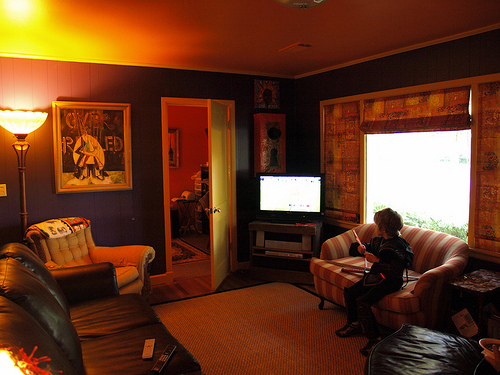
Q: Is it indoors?
A: Yes, it is indoors.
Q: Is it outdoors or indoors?
A: It is indoors.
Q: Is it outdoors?
A: No, it is indoors.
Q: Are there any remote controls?
A: Yes, there is a remote control.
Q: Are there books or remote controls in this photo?
A: Yes, there is a remote control.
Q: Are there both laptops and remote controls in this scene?
A: No, there is a remote control but no laptops.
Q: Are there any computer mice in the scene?
A: No, there are no computer mice.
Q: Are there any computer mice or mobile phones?
A: No, there are no computer mice or mobile phones.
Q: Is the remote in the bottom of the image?
A: Yes, the remote is in the bottom of the image.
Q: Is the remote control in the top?
A: No, the remote control is in the bottom of the image.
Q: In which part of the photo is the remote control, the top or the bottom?
A: The remote control is in the bottom of the image.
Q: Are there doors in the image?
A: Yes, there is a door.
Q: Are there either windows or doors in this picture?
A: Yes, there is a door.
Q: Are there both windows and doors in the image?
A: Yes, there are both a door and a window.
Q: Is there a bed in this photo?
A: No, there are no beds.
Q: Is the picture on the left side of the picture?
A: Yes, the picture is on the left of the image.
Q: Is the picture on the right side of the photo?
A: No, the picture is on the left of the image.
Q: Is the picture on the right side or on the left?
A: The picture is on the left of the image.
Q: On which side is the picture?
A: The picture is on the left of the image.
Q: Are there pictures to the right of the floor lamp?
A: Yes, there is a picture to the right of the floor lamp.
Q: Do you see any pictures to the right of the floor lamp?
A: Yes, there is a picture to the right of the floor lamp.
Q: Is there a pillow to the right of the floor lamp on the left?
A: No, there is a picture to the right of the floor lamp.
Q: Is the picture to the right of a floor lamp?
A: Yes, the picture is to the right of a floor lamp.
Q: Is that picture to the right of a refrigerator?
A: No, the picture is to the right of a floor lamp.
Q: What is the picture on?
A: The picture is on the wall.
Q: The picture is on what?
A: The picture is on the wall.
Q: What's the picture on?
A: The picture is on the wall.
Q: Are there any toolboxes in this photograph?
A: No, there are no toolboxes.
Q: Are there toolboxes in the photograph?
A: No, there are no toolboxes.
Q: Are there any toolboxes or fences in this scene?
A: No, there are no toolboxes or fences.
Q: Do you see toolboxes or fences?
A: No, there are no toolboxes or fences.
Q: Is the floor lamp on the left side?
A: Yes, the floor lamp is on the left of the image.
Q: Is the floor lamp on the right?
A: No, the floor lamp is on the left of the image.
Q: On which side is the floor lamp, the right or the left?
A: The floor lamp is on the left of the image.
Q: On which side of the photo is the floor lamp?
A: The floor lamp is on the left of the image.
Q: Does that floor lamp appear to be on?
A: Yes, the floor lamp is on.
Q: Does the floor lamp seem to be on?
A: Yes, the floor lamp is on.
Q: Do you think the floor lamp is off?
A: No, the floor lamp is on.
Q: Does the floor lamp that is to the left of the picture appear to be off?
A: No, the floor lamp is on.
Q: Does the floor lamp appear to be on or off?
A: The floor lamp is on.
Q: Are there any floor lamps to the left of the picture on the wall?
A: Yes, there is a floor lamp to the left of the picture.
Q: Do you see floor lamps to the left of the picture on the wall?
A: Yes, there is a floor lamp to the left of the picture.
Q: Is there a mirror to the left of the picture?
A: No, there is a floor lamp to the left of the picture.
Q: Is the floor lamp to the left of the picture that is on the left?
A: Yes, the floor lamp is to the left of the picture.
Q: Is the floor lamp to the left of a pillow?
A: No, the floor lamp is to the left of the picture.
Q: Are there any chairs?
A: Yes, there is a chair.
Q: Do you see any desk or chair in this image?
A: Yes, there is a chair.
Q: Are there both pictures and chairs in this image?
A: Yes, there are both a chair and a picture.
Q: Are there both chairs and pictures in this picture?
A: Yes, there are both a chair and a picture.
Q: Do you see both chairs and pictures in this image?
A: Yes, there are both a chair and a picture.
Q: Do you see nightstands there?
A: No, there are no nightstands.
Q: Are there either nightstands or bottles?
A: No, there are no nightstands or bottles.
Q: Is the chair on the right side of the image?
A: Yes, the chair is on the right of the image.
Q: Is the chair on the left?
A: No, the chair is on the right of the image.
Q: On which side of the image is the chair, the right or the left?
A: The chair is on the right of the image.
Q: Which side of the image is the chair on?
A: The chair is on the right of the image.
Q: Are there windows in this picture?
A: Yes, there is a window.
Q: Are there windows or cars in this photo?
A: Yes, there is a window.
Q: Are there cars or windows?
A: Yes, there is a window.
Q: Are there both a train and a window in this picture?
A: No, there is a window but no trains.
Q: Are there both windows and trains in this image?
A: No, there is a window but no trains.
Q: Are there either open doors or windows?
A: Yes, there is an open window.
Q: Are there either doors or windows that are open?
A: Yes, the window is open.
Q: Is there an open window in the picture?
A: Yes, there is an open window.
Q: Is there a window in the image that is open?
A: Yes, there is a window that is open.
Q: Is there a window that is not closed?
A: Yes, there is a open window.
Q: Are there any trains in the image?
A: No, there are no trains.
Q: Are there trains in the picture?
A: No, there are no trains.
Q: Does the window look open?
A: Yes, the window is open.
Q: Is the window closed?
A: No, the window is open.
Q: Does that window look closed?
A: No, the window is open.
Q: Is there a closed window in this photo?
A: No, there is a window but it is open.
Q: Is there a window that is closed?
A: No, there is a window but it is open.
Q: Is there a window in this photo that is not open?
A: No, there is a window but it is open.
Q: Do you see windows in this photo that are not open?
A: No, there is a window but it is open.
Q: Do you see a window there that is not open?
A: No, there is a window but it is open.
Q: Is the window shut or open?
A: The window is open.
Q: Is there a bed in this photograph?
A: No, there are no beds.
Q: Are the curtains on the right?
A: Yes, the curtains are on the right of the image.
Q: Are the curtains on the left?
A: No, the curtains are on the right of the image.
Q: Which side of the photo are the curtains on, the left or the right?
A: The curtains are on the right of the image.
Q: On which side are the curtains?
A: The curtains are on the right of the image.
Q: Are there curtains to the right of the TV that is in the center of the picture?
A: Yes, there are curtains to the right of the television.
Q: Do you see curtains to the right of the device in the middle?
A: Yes, there are curtains to the right of the television.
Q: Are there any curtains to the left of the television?
A: No, the curtains are to the right of the television.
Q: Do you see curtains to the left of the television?
A: No, the curtains are to the right of the television.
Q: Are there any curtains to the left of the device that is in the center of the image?
A: No, the curtains are to the right of the television.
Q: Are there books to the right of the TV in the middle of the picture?
A: No, there are curtains to the right of the television.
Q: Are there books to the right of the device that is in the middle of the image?
A: No, there are curtains to the right of the television.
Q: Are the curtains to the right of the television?
A: Yes, the curtains are to the right of the television.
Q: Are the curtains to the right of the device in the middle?
A: Yes, the curtains are to the right of the television.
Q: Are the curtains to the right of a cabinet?
A: No, the curtains are to the right of the television.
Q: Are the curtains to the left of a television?
A: No, the curtains are to the right of a television.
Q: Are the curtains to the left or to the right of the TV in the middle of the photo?
A: The curtains are to the right of the television.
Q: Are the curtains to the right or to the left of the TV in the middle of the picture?
A: The curtains are to the right of the television.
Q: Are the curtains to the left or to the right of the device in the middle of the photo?
A: The curtains are to the right of the television.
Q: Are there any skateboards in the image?
A: No, there are no skateboards.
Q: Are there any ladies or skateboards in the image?
A: No, there are no skateboards or ladies.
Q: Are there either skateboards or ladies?
A: No, there are no skateboards or ladies.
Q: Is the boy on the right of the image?
A: Yes, the boy is on the right of the image.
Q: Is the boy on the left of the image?
A: No, the boy is on the right of the image.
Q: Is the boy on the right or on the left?
A: The boy is on the right of the image.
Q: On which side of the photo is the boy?
A: The boy is on the right of the image.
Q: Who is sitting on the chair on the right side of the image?
A: The boy is sitting on the chair.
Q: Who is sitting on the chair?
A: The boy is sitting on the chair.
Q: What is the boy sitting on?
A: The boy is sitting on the chair.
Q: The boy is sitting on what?
A: The boy is sitting on the chair.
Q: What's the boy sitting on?
A: The boy is sitting on the chair.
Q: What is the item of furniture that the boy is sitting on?
A: The piece of furniture is a chair.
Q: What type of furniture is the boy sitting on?
A: The boy is sitting on the chair.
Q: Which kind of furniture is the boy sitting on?
A: The boy is sitting on the chair.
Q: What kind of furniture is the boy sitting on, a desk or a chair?
A: The boy is sitting on a chair.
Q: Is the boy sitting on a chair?
A: Yes, the boy is sitting on a chair.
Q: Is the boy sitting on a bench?
A: No, the boy is sitting on a chair.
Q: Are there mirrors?
A: No, there are no mirrors.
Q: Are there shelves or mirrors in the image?
A: No, there are no mirrors or shelves.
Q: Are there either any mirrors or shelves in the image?
A: No, there are no mirrors or shelves.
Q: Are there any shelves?
A: No, there are no shelves.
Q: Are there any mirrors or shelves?
A: No, there are no shelves or mirrors.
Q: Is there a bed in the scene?
A: No, there are no beds.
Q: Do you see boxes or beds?
A: No, there are no beds or boxes.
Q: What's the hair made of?
A: The hair is made of leather.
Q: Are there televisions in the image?
A: Yes, there is a television.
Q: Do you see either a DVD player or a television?
A: Yes, there is a television.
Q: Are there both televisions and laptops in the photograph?
A: No, there is a television but no laptops.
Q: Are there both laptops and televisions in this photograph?
A: No, there is a television but no laptops.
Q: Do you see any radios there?
A: No, there are no radios.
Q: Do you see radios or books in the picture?
A: No, there are no radios or books.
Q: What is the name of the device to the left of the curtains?
A: The device is a television.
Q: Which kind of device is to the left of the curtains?
A: The device is a television.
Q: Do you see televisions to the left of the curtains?
A: Yes, there is a television to the left of the curtains.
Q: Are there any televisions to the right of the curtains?
A: No, the television is to the left of the curtains.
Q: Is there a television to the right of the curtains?
A: No, the television is to the left of the curtains.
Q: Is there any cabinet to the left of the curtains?
A: No, there is a television to the left of the curtains.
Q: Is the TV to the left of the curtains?
A: Yes, the TV is to the left of the curtains.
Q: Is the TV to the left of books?
A: No, the TV is to the left of the curtains.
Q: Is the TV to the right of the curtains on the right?
A: No, the TV is to the left of the curtains.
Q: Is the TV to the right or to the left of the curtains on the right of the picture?
A: The TV is to the left of the curtains.